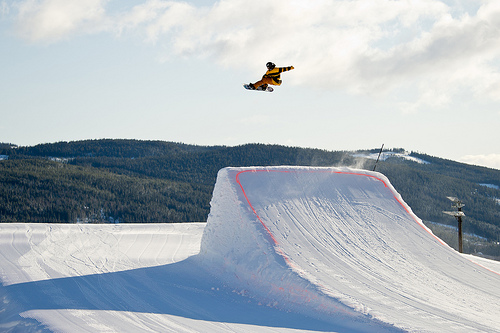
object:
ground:
[1, 165, 498, 331]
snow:
[2, 167, 495, 330]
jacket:
[260, 69, 287, 86]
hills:
[98, 138, 218, 212]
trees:
[66, 136, 166, 208]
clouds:
[3, 5, 497, 60]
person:
[244, 63, 297, 94]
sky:
[3, 0, 499, 168]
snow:
[359, 147, 426, 164]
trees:
[334, 142, 446, 174]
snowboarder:
[236, 55, 296, 97]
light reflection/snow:
[42, 219, 192, 264]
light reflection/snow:
[342, 221, 498, 326]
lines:
[219, 165, 500, 325]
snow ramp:
[191, 160, 497, 327]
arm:
[277, 64, 294, 73]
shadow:
[0, 247, 371, 330]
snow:
[8, 226, 133, 281]